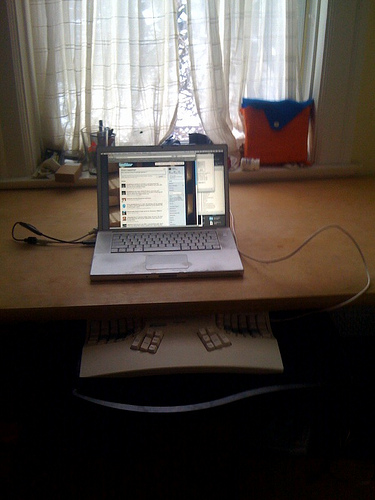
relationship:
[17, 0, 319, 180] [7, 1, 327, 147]
curtain front window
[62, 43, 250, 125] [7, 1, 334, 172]
sunlight on window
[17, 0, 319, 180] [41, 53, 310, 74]
curtain has stripes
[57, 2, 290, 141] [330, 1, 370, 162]
window on wall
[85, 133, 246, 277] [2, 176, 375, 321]
computer on computer desk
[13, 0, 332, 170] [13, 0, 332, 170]
background window on background window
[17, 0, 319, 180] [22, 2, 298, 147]
curtain on window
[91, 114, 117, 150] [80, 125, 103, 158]
pens on glass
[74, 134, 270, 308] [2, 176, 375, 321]
laptop on computer desk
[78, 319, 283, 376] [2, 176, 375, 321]
keyboard under computer desk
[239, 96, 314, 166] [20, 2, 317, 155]
bag front window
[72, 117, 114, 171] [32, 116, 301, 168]
glass in sill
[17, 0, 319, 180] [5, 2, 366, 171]
curtain hanging in window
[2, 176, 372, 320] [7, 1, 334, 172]
computer desk in front of window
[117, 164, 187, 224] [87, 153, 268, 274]
twitter on computer